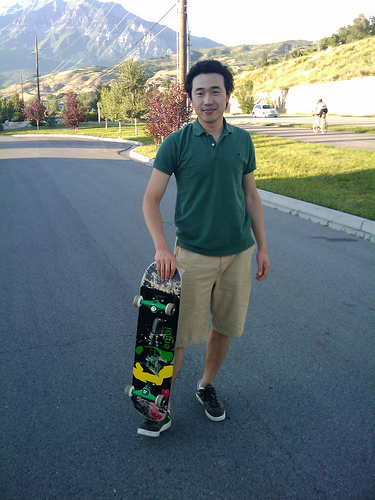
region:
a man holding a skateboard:
[137, 55, 269, 422]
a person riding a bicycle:
[307, 96, 331, 131]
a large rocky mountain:
[0, 0, 163, 59]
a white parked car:
[249, 101, 279, 117]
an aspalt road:
[2, 120, 143, 227]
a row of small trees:
[25, 62, 142, 134]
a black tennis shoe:
[193, 377, 228, 422]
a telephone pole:
[30, 37, 45, 122]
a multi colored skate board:
[128, 260, 183, 421]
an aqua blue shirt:
[155, 123, 258, 251]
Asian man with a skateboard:
[122, 59, 287, 441]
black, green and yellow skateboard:
[126, 259, 195, 435]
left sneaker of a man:
[190, 379, 239, 433]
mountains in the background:
[1, 1, 182, 76]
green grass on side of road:
[272, 147, 370, 194]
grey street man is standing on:
[280, 250, 372, 481]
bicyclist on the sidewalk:
[302, 87, 334, 142]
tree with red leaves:
[57, 82, 91, 132]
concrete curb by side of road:
[276, 199, 369, 239]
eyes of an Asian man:
[191, 83, 225, 99]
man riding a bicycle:
[308, 95, 327, 133]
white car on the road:
[248, 99, 273, 115]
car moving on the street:
[248, 100, 275, 115]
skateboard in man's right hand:
[123, 256, 178, 421]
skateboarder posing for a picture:
[122, 56, 266, 433]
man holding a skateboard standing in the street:
[124, 56, 266, 434]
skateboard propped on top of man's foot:
[120, 255, 180, 435]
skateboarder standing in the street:
[15, 56, 273, 491]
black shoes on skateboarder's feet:
[135, 380, 227, 434]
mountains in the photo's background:
[0, 0, 227, 87]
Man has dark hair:
[175, 53, 237, 98]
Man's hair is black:
[184, 54, 236, 97]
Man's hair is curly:
[183, 53, 240, 99]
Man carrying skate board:
[124, 241, 194, 442]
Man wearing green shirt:
[152, 117, 286, 260]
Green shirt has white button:
[203, 132, 230, 159]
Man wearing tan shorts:
[160, 226, 262, 356]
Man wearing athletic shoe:
[194, 371, 231, 427]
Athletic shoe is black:
[196, 375, 230, 426]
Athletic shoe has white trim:
[194, 375, 233, 429]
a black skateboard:
[122, 255, 182, 422]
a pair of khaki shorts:
[169, 240, 256, 345]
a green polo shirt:
[151, 116, 258, 255]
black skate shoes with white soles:
[136, 381, 227, 437]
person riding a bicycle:
[311, 97, 330, 133]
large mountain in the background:
[1, 1, 223, 72]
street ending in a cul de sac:
[0, 129, 371, 495]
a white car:
[249, 102, 279, 122]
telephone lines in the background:
[7, 2, 192, 121]